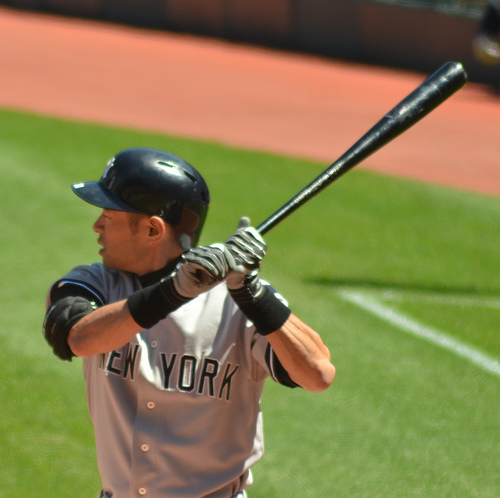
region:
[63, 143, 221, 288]
A side view of a players head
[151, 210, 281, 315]
Player is wearing gloves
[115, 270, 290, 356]
Player is wearing black sweatbands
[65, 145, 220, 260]
Player is wearing a black helmet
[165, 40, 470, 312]
Player is holding a baseball bat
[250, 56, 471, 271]
Baseball bat is black in color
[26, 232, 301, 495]
Baseball player's outfit is gray and black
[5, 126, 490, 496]
Player is on the baseball field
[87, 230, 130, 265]
Baseball player's mouth is open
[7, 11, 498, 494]
Photo was taken in the daytime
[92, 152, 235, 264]
man has black helmet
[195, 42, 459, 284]
player holds black bat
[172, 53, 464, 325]
player is left handed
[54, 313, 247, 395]
letters on shirt are black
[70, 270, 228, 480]
shirt is grey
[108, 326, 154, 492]
buttons on shirt are white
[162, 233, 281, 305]
player wears black and white gloves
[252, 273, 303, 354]
player wears black wristband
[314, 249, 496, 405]
white line on field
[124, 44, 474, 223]
foul ground dirt is red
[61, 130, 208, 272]
player wearing plastic black helmet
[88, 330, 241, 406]
New York embroidered on jersey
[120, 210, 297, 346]
gloves on players hands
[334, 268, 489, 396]
white lines painted on grass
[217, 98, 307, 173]
grass and red dirt field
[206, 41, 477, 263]
black metal baseball bat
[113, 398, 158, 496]
white buttons on gray jersey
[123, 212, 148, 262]
man has short trimmed sideburns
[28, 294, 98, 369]
black upper arm brace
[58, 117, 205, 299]
man looking ahead at pitcher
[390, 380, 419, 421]
Small patch of green grass on baseball field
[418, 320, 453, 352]
White solid line on baseball field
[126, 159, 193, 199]
Black helmet of baseball player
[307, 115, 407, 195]
Black bat of the batter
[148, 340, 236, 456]
Gray New York Yankee team shirt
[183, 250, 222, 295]
Gray left glove of baseball player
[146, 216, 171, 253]
Left ear of batter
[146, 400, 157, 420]
White button on gray uniform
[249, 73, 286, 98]
Small patch of orange dirt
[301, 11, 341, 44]
Gray pad in the background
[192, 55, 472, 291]
black baseball bat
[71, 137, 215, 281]
baseball player wearing black helmet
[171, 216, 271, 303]
grey and black baseball gloves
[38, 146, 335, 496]
man wearing a grey baseball uniform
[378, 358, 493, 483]
section of green grass on field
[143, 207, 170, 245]
man's left ear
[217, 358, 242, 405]
black letter K on uniform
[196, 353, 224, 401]
black letter R on uniform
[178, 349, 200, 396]
black letter O on uniform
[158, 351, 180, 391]
black letter Y on uniform